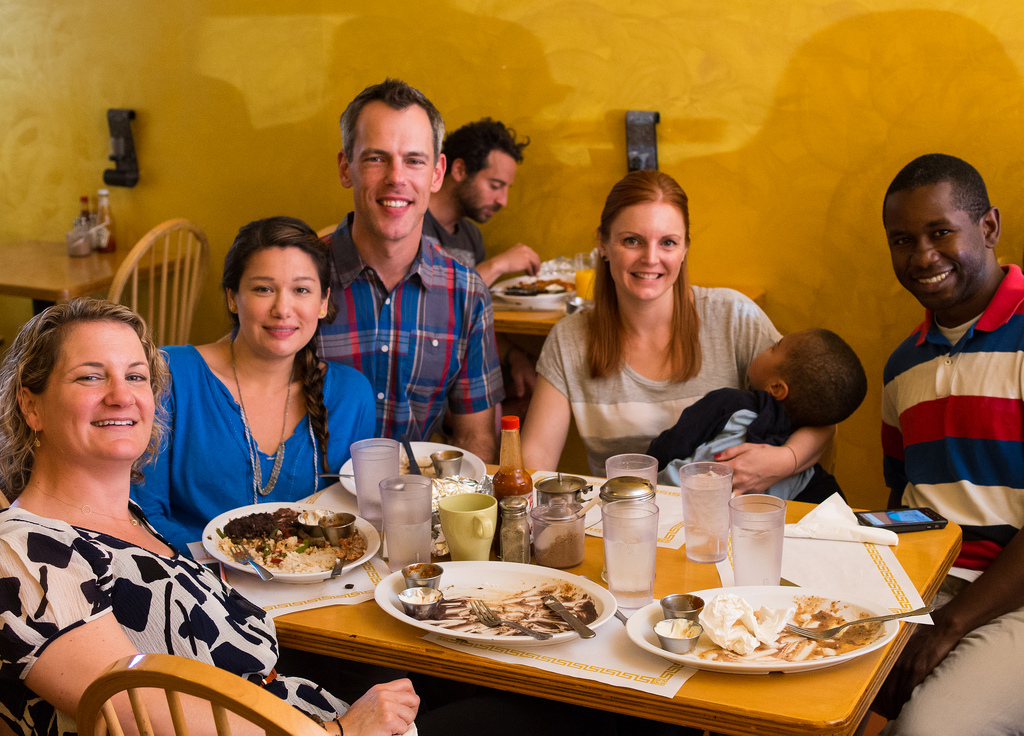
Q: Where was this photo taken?
A: At the family luncheon.